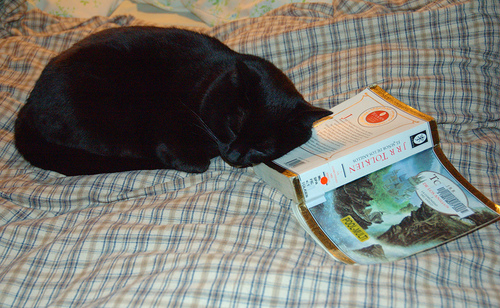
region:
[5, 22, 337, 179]
black cat appreciates bedding; pillow made of hobbits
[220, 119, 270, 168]
two shut eyes, two furry eyelids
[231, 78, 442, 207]
cat uses large softcover book as large hard pillow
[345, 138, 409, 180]
'j r r tolkien' in all caps, in red, on book's white spine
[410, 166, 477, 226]
idiot barcode sticker pasted on top of book's title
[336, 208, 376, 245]
'pool' in caps, along w/ some fairly undecipherable letters, on narrow yellow sticker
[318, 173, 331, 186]
red dot sticker on spine; red dot logo on back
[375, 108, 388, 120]
red circle logo on back has inner white circle inside it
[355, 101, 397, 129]
red logo circle on back encircled by white circle, lined in grey, w/ yellow orange type inside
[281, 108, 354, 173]
a giant drop cap red 'j' on rear cover, w/ yet another barcode near its bottom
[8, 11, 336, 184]
black furry cat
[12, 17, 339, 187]
black cat laying on bed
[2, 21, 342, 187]
cat laying on bed with plaid sheets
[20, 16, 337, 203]
cat laying on novel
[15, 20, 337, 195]
sleeping black cat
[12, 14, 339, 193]
domesticated feline with black fur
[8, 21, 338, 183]
small furry mammal with four legs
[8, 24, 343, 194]
black cat with long tail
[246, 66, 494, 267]
white book with gold border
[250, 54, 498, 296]
novel checked out from a library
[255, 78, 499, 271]
The book the cat is lying on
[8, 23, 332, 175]
The cat on the bed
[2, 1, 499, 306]
The blanket on the bed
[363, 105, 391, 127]
The red circle on the back of the book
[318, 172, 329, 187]
The red circle on the spine of the book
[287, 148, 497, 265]
The cover of the book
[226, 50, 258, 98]
The cat's right ear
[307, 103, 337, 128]
The cat's left ear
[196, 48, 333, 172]
The head of the cat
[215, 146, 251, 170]
The nose of the cat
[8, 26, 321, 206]
Cat is black color.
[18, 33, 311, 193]
Cat is lying in cot.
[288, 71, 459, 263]
Book is in bed.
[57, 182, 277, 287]
bedsheet is grey color.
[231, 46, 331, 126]
two pointed ears for cat.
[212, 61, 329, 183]
Cat head is in book.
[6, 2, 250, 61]
Light reflection is seen in bed.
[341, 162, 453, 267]
Waterfalls picture is the outer cover.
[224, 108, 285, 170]
Cat eyes are closed.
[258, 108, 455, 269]
Book is inverted in bed.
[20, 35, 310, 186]
The black cat is sleeping.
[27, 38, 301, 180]
The black cat is sleeping on the bed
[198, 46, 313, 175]
The black cat's head is on the book.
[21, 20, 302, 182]
The black cat is sleeping on a plaid blanket.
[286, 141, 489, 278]
The book is on the bed.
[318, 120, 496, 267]
The book is laying next to the black cat.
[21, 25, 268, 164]
The black cat's coat is smooth.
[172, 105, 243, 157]
The cat's whiskers are white and thin.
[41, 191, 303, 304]
The blanket is wrinkled.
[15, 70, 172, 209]
The cat's tail is curled under its body.